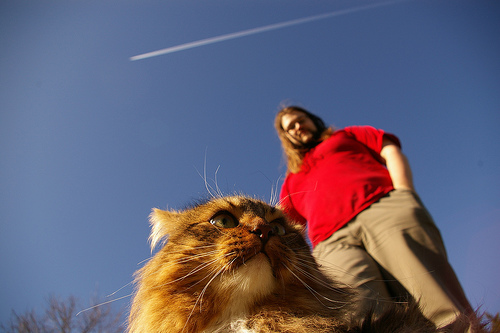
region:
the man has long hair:
[271, 94, 339, 167]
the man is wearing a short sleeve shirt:
[266, 120, 399, 244]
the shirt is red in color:
[276, 125, 397, 241]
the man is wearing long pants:
[310, 185, 487, 324]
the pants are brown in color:
[312, 195, 475, 331]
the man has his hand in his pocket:
[353, 133, 435, 203]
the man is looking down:
[266, 105, 326, 147]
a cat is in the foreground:
[132, 185, 354, 327]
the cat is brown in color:
[128, 194, 345, 329]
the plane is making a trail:
[126, 11, 367, 72]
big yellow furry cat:
[115, 193, 350, 331]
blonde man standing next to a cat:
[261, 102, 478, 330]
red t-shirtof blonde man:
[268, 116, 399, 246]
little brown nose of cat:
[247, 215, 272, 237]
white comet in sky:
[130, 2, 358, 82]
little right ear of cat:
[148, 201, 198, 245]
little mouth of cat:
[232, 242, 300, 273]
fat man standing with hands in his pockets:
[260, 109, 472, 331]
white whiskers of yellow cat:
[162, 243, 349, 321]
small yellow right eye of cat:
[207, 208, 234, 226]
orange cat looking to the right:
[70, 161, 397, 331]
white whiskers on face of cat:
[72, 236, 244, 331]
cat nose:
[250, 220, 274, 247]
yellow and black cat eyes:
[198, 199, 298, 251]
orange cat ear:
[142, 194, 200, 256]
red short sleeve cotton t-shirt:
[262, 124, 412, 253]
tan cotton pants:
[301, 185, 485, 330]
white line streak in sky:
[120, 1, 367, 64]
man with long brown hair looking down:
[242, 103, 480, 331]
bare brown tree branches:
[3, 291, 125, 329]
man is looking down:
[245, 90, 485, 331]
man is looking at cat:
[245, 81, 482, 328]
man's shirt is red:
[262, 123, 417, 248]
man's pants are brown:
[297, 185, 481, 331]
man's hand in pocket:
[392, 178, 429, 222]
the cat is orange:
[101, 180, 368, 330]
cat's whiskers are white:
[83, 230, 378, 324]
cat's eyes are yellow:
[203, 200, 319, 240]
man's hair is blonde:
[255, 90, 349, 167]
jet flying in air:
[109, 0, 402, 67]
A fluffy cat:
[122, 189, 354, 331]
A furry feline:
[126, 195, 353, 331]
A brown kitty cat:
[123, 190, 362, 331]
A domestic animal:
[130, 197, 360, 332]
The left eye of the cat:
[197, 199, 242, 229]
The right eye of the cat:
[265, 213, 292, 237]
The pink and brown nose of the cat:
[246, 218, 276, 239]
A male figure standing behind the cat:
[118, 77, 478, 332]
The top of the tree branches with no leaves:
[6, 293, 131, 331]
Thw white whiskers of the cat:
[188, 151, 230, 195]